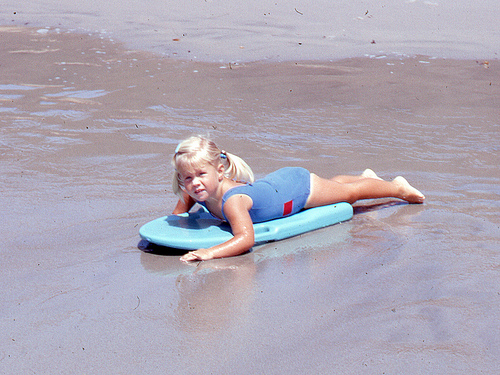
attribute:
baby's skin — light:
[164, 133, 427, 264]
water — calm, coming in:
[1, 1, 500, 74]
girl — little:
[150, 136, 441, 266]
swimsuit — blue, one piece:
[204, 165, 314, 228]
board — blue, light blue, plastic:
[134, 197, 365, 256]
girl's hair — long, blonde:
[170, 134, 254, 198]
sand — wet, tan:
[1, 27, 499, 375]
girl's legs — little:
[304, 165, 428, 212]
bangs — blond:
[175, 153, 210, 175]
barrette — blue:
[218, 151, 229, 160]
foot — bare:
[390, 173, 431, 207]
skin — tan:
[303, 164, 427, 208]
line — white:
[303, 171, 317, 209]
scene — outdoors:
[1, 0, 500, 374]